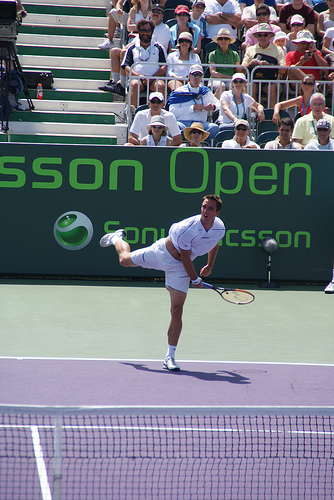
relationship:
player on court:
[98, 194, 226, 374] [4, 357, 330, 498]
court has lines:
[4, 357, 330, 498] [1, 357, 333, 498]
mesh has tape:
[4, 414, 332, 499] [1, 403, 333, 418]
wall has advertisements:
[1, 141, 331, 282] [2, 146, 314, 252]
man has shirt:
[285, 30, 326, 82] [284, 49, 329, 78]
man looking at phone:
[285, 30, 326, 82] [305, 45, 313, 59]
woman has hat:
[166, 6, 201, 52] [172, 2, 189, 19]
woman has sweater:
[166, 6, 201, 52] [168, 23, 202, 46]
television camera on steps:
[1, 2, 33, 135] [5, 3, 125, 145]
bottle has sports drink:
[33, 82, 45, 99] [37, 91, 44, 101]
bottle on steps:
[33, 82, 45, 99] [5, 3, 125, 145]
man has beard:
[122, 20, 165, 110] [136, 31, 154, 43]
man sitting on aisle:
[122, 20, 165, 110] [5, 3, 125, 145]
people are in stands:
[105, 4, 330, 151] [1, 2, 330, 150]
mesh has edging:
[4, 414, 332, 499] [1, 403, 333, 418]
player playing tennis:
[98, 194, 226, 374] [8, 191, 331, 500]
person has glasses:
[205, 29, 244, 78] [214, 37, 231, 43]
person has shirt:
[205, 29, 244, 78] [208, 48, 239, 75]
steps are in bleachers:
[5, 3, 125, 145] [1, 2, 330, 150]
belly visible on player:
[163, 237, 184, 264] [98, 194, 226, 374]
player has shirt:
[98, 194, 226, 374] [171, 216, 226, 261]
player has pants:
[98, 194, 226, 374] [130, 238, 194, 293]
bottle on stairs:
[33, 82, 45, 99] [5, 3, 125, 145]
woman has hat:
[178, 122, 211, 148] [180, 122, 211, 145]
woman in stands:
[178, 122, 211, 148] [1, 2, 330, 150]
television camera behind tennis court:
[1, 2, 33, 135] [3, 281, 333, 498]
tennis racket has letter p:
[192, 279, 256, 306] [227, 291, 248, 303]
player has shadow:
[98, 194, 226, 374] [123, 361, 251, 388]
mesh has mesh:
[4, 414, 332, 499] [4, 414, 332, 499]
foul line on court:
[1, 353, 332, 368] [4, 357, 330, 498]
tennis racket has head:
[192, 279, 256, 306] [219, 285, 256, 308]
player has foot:
[98, 194, 226, 374] [160, 357, 181, 374]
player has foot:
[98, 194, 226, 374] [100, 229, 125, 249]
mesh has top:
[4, 414, 332, 499] [1, 403, 333, 418]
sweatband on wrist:
[189, 278, 201, 286] [191, 276, 203, 286]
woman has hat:
[218, 72, 264, 128] [230, 71, 248, 84]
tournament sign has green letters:
[2, 146, 311, 254] [0, 146, 313, 252]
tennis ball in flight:
[261, 238, 281, 253] [260, 236, 279, 255]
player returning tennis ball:
[98, 194, 226, 374] [261, 238, 281, 253]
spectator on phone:
[285, 30, 326, 82] [305, 45, 313, 59]